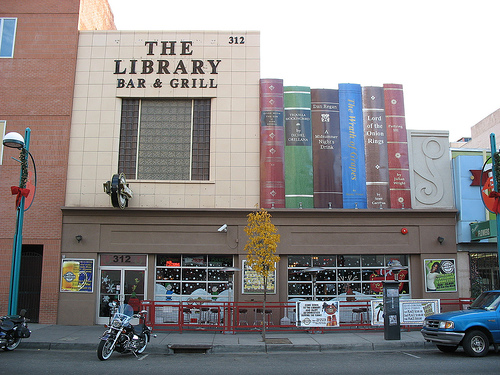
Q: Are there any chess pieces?
A: No, there are no chess pieces.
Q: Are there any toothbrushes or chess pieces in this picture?
A: No, there are no chess pieces or toothbrushes.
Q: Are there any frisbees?
A: No, there are no frisbees.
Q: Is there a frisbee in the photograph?
A: No, there are no frisbees.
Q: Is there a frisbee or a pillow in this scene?
A: No, there are no frisbees or pillows.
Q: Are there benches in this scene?
A: No, there are no benches.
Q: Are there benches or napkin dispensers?
A: No, there are no benches or napkin dispensers.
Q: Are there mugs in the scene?
A: Yes, there is a mug.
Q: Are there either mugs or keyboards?
A: Yes, there is a mug.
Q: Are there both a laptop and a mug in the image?
A: No, there is a mug but no laptops.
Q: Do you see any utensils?
A: No, there are no utensils.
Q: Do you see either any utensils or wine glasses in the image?
A: No, there are no utensils or wine glasses.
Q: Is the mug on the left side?
A: Yes, the mug is on the left of the image.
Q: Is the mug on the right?
A: No, the mug is on the left of the image.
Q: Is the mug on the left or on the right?
A: The mug is on the left of the image.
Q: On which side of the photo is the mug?
A: The mug is on the left of the image.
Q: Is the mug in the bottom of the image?
A: Yes, the mug is in the bottom of the image.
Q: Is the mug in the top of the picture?
A: No, the mug is in the bottom of the image.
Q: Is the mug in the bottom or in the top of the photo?
A: The mug is in the bottom of the image.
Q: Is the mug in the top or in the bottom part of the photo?
A: The mug is in the bottom of the image.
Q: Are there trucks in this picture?
A: Yes, there is a truck.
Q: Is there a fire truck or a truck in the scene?
A: Yes, there is a truck.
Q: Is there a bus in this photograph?
A: No, there are no buses.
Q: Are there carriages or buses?
A: No, there are no buses or carriages.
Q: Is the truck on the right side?
A: Yes, the truck is on the right of the image.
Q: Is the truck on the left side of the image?
A: No, the truck is on the right of the image.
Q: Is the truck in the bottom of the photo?
A: Yes, the truck is in the bottom of the image.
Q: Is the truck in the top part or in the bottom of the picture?
A: The truck is in the bottom of the image.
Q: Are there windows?
A: Yes, there is a window.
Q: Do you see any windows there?
A: Yes, there is a window.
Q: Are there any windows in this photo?
A: Yes, there is a window.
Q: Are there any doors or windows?
A: Yes, there is a window.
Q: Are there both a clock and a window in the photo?
A: No, there is a window but no clocks.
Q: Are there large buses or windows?
A: Yes, there is a large window.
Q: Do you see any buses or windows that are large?
A: Yes, the window is large.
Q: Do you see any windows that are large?
A: Yes, there is a large window.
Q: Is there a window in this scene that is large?
A: Yes, there is a window that is large.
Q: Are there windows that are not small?
A: Yes, there is a large window.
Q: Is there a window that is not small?
A: Yes, there is a large window.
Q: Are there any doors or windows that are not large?
A: No, there is a window but it is large.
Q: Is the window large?
A: Yes, the window is large.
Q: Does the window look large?
A: Yes, the window is large.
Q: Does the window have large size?
A: Yes, the window is large.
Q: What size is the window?
A: The window is large.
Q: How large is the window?
A: The window is large.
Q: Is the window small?
A: No, the window is large.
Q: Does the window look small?
A: No, the window is large.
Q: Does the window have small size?
A: No, the window is large.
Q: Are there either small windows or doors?
A: No, there is a window but it is large.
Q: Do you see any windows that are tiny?
A: No, there is a window but it is large.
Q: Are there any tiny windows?
A: No, there is a window but it is large.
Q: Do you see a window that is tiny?
A: No, there is a window but it is large.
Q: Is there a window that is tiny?
A: No, there is a window but it is large.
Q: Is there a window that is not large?
A: No, there is a window but it is large.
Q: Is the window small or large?
A: The window is large.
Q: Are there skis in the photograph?
A: No, there are no skis.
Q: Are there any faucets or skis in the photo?
A: No, there are no skis or faucets.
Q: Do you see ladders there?
A: No, there are no ladders.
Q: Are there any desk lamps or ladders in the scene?
A: No, there are no ladders or desk lamps.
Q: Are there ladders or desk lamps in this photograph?
A: No, there are no ladders or desk lamps.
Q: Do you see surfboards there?
A: No, there are no surfboards.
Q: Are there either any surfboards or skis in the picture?
A: No, there are no surfboards or skis.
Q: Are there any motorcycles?
A: Yes, there is a motorcycle.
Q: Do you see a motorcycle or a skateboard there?
A: Yes, there is a motorcycle.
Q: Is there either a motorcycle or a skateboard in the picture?
A: Yes, there is a motorcycle.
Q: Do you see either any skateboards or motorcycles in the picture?
A: Yes, there is a motorcycle.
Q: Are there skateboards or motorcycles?
A: Yes, there is a motorcycle.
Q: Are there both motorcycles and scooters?
A: No, there is a motorcycle but no scooters.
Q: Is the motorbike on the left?
A: Yes, the motorbike is on the left of the image.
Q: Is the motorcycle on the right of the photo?
A: No, the motorcycle is on the left of the image.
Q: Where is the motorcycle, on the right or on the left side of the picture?
A: The motorcycle is on the left of the image.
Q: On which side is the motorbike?
A: The motorbike is on the left of the image.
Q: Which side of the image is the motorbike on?
A: The motorbike is on the left of the image.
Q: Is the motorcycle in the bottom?
A: Yes, the motorcycle is in the bottom of the image.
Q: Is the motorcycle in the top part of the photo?
A: No, the motorcycle is in the bottom of the image.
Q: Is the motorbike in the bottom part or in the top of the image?
A: The motorbike is in the bottom of the image.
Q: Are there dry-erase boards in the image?
A: No, there are no dry-erase boards.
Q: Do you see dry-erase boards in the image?
A: No, there are no dry-erase boards.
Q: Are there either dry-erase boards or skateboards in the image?
A: No, there are no dry-erase boards or skateboards.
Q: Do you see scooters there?
A: No, there are no scooters.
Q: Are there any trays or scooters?
A: No, there are no scooters or trays.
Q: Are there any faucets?
A: No, there are no faucets.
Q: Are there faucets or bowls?
A: No, there are no faucets or bowls.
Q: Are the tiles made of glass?
A: Yes, the tiles are made of glass.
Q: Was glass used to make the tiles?
A: Yes, the tiles are made of glass.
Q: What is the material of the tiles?
A: The tiles are made of glass.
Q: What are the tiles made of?
A: The tiles are made of glass.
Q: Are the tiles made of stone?
A: No, the tiles are made of glass.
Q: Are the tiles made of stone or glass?
A: The tiles are made of glass.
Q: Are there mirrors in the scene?
A: No, there are no mirrors.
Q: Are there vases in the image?
A: No, there are no vases.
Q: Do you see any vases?
A: No, there are no vases.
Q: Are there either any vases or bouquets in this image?
A: No, there are no vases or bouquets.